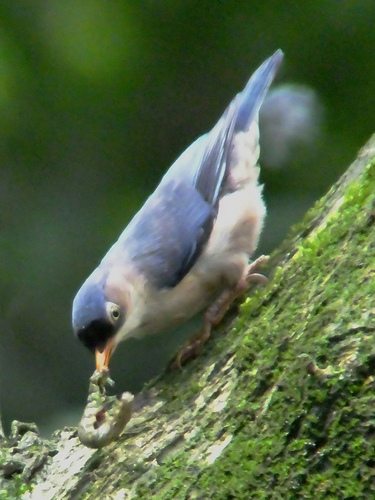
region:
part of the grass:
[292, 441, 304, 453]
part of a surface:
[223, 442, 233, 455]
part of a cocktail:
[121, 400, 132, 404]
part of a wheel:
[215, 413, 223, 424]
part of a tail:
[98, 427, 117, 448]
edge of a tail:
[121, 380, 130, 390]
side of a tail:
[118, 414, 126, 424]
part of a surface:
[27, 417, 40, 437]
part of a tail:
[107, 423, 125, 441]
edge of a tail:
[91, 422, 112, 435]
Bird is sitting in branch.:
[80, 179, 296, 327]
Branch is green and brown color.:
[155, 385, 318, 470]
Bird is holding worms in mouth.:
[64, 301, 159, 436]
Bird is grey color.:
[45, 172, 245, 331]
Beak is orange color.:
[79, 346, 139, 393]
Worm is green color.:
[73, 374, 142, 444]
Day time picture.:
[24, 34, 363, 467]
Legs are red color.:
[158, 265, 300, 364]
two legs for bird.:
[170, 267, 315, 366]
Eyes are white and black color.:
[102, 300, 128, 329]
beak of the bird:
[87, 344, 121, 370]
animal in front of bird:
[64, 359, 150, 455]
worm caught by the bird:
[55, 356, 143, 449]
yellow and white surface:
[192, 321, 300, 420]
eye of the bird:
[97, 293, 131, 334]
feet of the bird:
[197, 241, 285, 335]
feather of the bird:
[150, 151, 243, 267]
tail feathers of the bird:
[222, 34, 297, 114]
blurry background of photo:
[31, 15, 130, 114]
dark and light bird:
[66, 178, 255, 358]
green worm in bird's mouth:
[77, 368, 133, 448]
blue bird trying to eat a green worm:
[70, 46, 285, 449]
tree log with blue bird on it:
[0, 131, 374, 497]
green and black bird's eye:
[110, 304, 120, 319]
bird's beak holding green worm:
[93, 347, 112, 379]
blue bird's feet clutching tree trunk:
[164, 253, 270, 373]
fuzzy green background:
[0, 0, 373, 435]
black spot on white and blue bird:
[77, 317, 114, 353]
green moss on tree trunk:
[201, 435, 274, 490]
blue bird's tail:
[207, 47, 284, 134]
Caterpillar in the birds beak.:
[75, 362, 138, 448]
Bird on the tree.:
[46, 46, 267, 377]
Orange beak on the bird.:
[83, 337, 114, 378]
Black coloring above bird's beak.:
[65, 309, 131, 374]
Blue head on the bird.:
[68, 272, 132, 360]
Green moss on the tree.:
[131, 161, 372, 497]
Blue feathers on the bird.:
[62, 50, 283, 332]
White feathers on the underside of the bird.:
[99, 112, 270, 360]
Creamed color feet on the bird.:
[168, 253, 273, 375]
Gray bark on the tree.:
[47, 435, 89, 498]